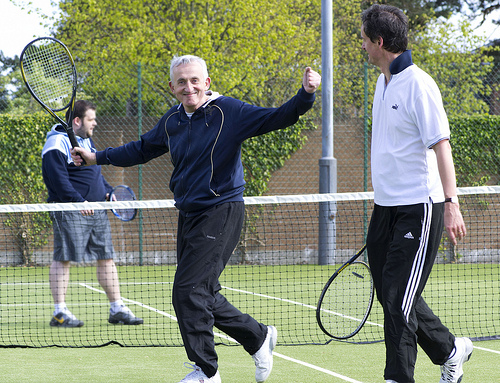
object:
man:
[350, 5, 477, 383]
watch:
[444, 196, 460, 204]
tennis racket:
[18, 36, 87, 168]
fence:
[0, 58, 498, 265]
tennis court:
[1, 264, 498, 380]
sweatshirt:
[41, 123, 116, 214]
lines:
[220, 282, 382, 327]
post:
[317, 2, 338, 267]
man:
[42, 96, 144, 328]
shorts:
[43, 198, 115, 262]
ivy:
[0, 113, 61, 252]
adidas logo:
[403, 230, 415, 239]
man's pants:
[360, 200, 452, 381]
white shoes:
[251, 324, 280, 382]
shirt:
[368, 50, 452, 210]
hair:
[168, 54, 209, 80]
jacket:
[93, 83, 318, 216]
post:
[132, 56, 146, 268]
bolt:
[329, 214, 335, 220]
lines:
[76, 280, 178, 323]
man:
[66, 52, 323, 381]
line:
[273, 350, 366, 383]